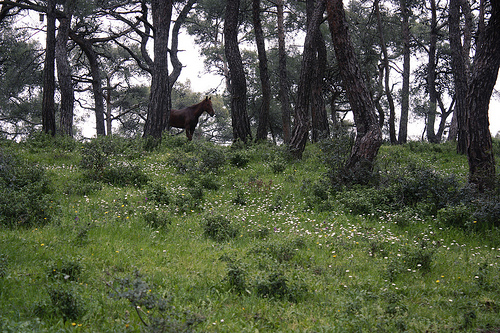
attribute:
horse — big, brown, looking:
[166, 94, 216, 142]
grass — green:
[1, 132, 499, 332]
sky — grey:
[0, 2, 499, 150]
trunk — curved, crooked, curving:
[462, 3, 499, 189]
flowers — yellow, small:
[434, 275, 463, 287]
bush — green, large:
[0, 150, 59, 231]